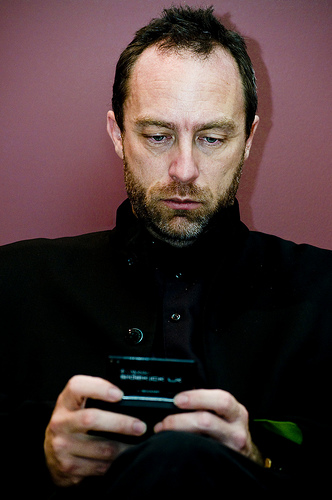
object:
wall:
[1, 1, 332, 251]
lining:
[254, 414, 306, 450]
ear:
[104, 108, 123, 163]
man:
[1, 4, 332, 499]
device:
[89, 341, 198, 443]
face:
[117, 42, 252, 243]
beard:
[123, 159, 244, 250]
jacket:
[1, 197, 332, 499]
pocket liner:
[246, 412, 304, 449]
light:
[127, 327, 146, 343]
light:
[104, 352, 198, 367]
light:
[114, 390, 172, 400]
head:
[104, 3, 261, 249]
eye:
[199, 133, 228, 148]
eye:
[140, 130, 171, 148]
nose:
[168, 126, 199, 185]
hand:
[43, 372, 149, 490]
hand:
[152, 386, 262, 465]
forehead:
[127, 38, 245, 119]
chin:
[148, 203, 211, 241]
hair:
[110, 4, 258, 143]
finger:
[172, 387, 241, 424]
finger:
[152, 411, 235, 442]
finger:
[58, 372, 125, 407]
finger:
[62, 406, 148, 439]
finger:
[64, 435, 131, 463]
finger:
[64, 450, 110, 480]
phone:
[85, 348, 198, 442]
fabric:
[250, 416, 305, 449]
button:
[172, 266, 186, 284]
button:
[170, 309, 185, 324]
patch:
[185, 216, 205, 241]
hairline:
[113, 17, 249, 142]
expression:
[130, 100, 240, 235]